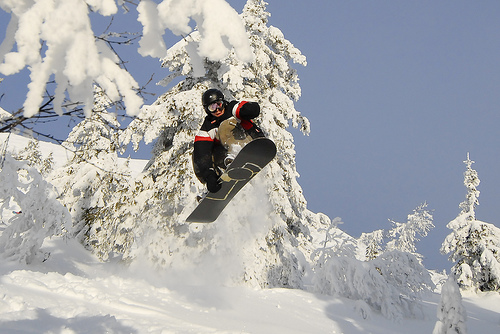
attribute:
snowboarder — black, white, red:
[181, 87, 271, 201]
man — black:
[191, 87, 265, 201]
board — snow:
[181, 134, 276, 224]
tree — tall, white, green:
[434, 158, 498, 297]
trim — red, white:
[232, 103, 242, 112]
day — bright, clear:
[6, 2, 498, 329]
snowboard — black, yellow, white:
[184, 136, 277, 222]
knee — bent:
[213, 118, 238, 136]